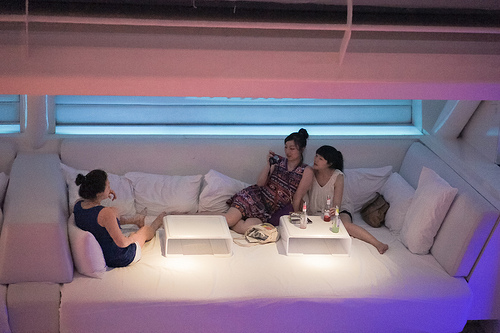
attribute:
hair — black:
[72, 167, 108, 204]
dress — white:
[304, 169, 344, 216]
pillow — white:
[67, 212, 105, 276]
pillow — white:
[65, 167, 142, 221]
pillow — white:
[125, 173, 200, 215]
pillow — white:
[200, 174, 250, 217]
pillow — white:
[339, 166, 388, 211]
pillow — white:
[378, 170, 408, 227]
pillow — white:
[398, 163, 448, 254]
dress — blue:
[73, 201, 143, 265]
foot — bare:
[373, 233, 393, 263]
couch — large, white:
[4, 135, 492, 330]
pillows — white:
[344, 159, 446, 260]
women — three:
[66, 124, 397, 275]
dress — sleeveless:
[226, 150, 311, 233]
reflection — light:
[57, 121, 420, 141]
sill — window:
[54, 119, 426, 140]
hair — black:
[312, 143, 355, 169]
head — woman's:
[315, 144, 340, 177]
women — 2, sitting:
[229, 117, 396, 269]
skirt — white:
[304, 205, 348, 225]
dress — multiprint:
[218, 149, 313, 229]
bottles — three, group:
[290, 193, 344, 233]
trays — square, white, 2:
[154, 204, 354, 261]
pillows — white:
[63, 161, 457, 275]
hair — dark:
[72, 162, 106, 205]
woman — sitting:
[66, 161, 174, 275]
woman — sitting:
[222, 121, 310, 238]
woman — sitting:
[308, 140, 390, 260]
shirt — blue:
[73, 196, 122, 256]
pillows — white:
[389, 160, 489, 280]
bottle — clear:
[290, 188, 322, 229]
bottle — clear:
[317, 200, 347, 245]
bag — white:
[228, 213, 278, 245]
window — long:
[3, 96, 430, 145]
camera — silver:
[261, 145, 293, 177]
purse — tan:
[348, 179, 395, 228]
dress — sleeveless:
[75, 196, 139, 267]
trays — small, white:
[158, 211, 359, 251]